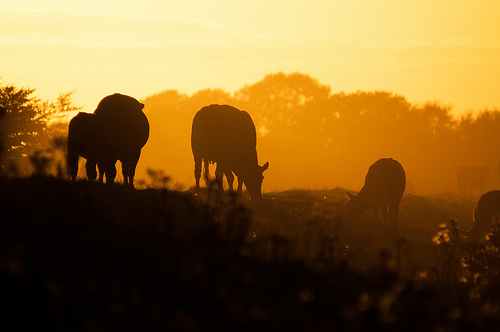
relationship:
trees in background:
[2, 85, 63, 148] [3, 35, 121, 98]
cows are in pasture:
[60, 90, 144, 190] [53, 177, 495, 223]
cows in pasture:
[60, 90, 144, 190] [53, 177, 495, 223]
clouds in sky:
[10, 9, 239, 55] [0, 1, 499, 80]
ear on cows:
[134, 98, 150, 113] [60, 90, 144, 190]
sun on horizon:
[0, 9, 9, 19] [5, 58, 234, 91]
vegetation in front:
[192, 214, 354, 278] [186, 275, 393, 328]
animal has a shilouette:
[191, 102, 267, 210] [186, 101, 268, 199]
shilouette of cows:
[186, 101, 268, 199] [60, 90, 144, 190]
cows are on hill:
[60, 90, 144, 190] [23, 177, 485, 224]